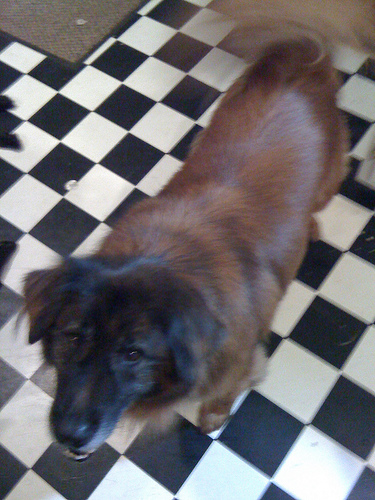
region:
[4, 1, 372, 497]
black and white floor.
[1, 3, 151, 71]
Rug on the floor.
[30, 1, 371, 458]
Dog standing on the floor.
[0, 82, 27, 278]
black paws on the floor.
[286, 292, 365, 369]
black square on the floor.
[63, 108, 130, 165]
white square on the floor.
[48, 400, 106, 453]
Black nose on the dog.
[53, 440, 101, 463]
white teeth on the dog.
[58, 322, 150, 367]
Brown eyes on the dog.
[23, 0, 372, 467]
Brown hair on the dog.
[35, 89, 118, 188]
the floor is tile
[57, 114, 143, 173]
the pattern is checkered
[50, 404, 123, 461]
snout of the dog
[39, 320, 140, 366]
eyes of the dog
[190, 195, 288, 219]
fur on the dog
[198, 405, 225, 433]
paw of the dog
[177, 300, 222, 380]
ear of the dog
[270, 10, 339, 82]
the tail is wagging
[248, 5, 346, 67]
tail on the dog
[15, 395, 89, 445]
nose of the dog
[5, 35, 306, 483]
dog on the floor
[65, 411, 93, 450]
nose of the dog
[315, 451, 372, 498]
the floor is tile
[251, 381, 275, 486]
the pattern is checkered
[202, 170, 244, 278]
fur of the dog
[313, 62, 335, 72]
back of the dog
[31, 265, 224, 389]
dog has black ears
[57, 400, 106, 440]
dog has black nose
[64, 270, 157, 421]
dog has black face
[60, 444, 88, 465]
dog has white teeth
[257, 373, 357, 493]
black and white floor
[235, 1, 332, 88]
dog has brown tail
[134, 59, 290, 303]
dog has brown back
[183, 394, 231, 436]
dog has brown paw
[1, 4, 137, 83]
brown rug on floor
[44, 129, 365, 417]
dog standing on black and white floor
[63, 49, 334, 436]
dog's body is brown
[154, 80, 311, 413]
dog's body is brown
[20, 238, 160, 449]
the dog's face is black